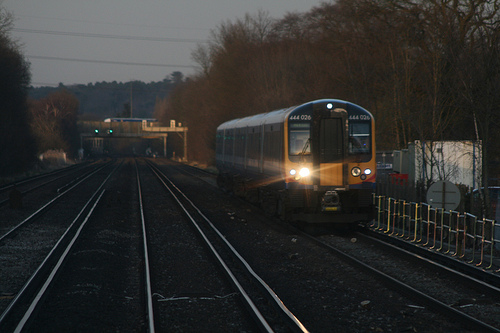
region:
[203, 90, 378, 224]
train on a track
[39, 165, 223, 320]
tracks without trains on them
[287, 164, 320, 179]
light on the train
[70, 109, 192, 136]
overpass with vehicles on it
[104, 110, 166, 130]
vehicle on the overpass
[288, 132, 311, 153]
window on front of train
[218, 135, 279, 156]
window on side of train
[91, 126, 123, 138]
lights on the overpass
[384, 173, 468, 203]
fence near the tracks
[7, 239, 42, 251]
rocks on the track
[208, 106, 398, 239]
a commuter train going on the tracks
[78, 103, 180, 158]
a bridge over the tracks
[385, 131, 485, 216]
green transformer boxes next to the tracks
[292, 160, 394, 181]
headlights on the commuter train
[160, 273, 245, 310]
broken limbs from tree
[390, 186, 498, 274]
metal fence along tracks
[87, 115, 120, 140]
stop light on the bridge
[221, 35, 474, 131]
trees on the side of the tracks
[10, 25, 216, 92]
power lines over the tracks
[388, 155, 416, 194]
red warning on the green box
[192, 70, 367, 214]
train on the track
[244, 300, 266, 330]
part of the metal train track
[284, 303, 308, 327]
part of the metal train track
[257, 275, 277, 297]
part of the metal train track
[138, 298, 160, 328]
part of the metal train track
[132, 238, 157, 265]
part of the metal train track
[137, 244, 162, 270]
part of the metal train track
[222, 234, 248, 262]
part of the metal train track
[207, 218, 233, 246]
part of the metal train track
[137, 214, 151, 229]
part of the metal train track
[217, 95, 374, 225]
train on the right train track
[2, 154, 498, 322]
several train tracks running parallel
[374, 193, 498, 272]
metal railing beside the train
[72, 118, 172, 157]
bridge over the train tracks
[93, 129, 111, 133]
two green lights over the tracks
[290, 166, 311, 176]
a bright headlight on train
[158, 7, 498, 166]
trees on the right side of track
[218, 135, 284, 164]
passenger windows on the side of the train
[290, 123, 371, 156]
two front windows on train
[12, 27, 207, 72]
black power lines over the tracks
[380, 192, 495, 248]
a fence next to the train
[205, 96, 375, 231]
a train on the tracks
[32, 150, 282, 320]
the railroad tracks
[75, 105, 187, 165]
a bridge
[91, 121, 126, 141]
lights over the tracks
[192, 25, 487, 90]
a tree next to the train tracks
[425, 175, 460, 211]
a sign on the tracks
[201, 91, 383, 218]
a blue and yellow train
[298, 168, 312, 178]
a light on the train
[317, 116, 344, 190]
the front door on the train